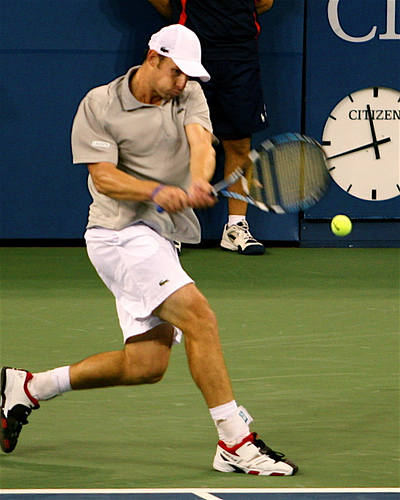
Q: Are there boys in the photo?
A: No, there are no boys.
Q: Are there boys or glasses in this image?
A: No, there are no boys or glasses.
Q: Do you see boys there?
A: No, there are no boys.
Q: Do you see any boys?
A: No, there are no boys.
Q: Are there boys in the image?
A: No, there are no boys.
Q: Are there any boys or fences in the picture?
A: No, there are no boys or fences.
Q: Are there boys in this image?
A: No, there are no boys.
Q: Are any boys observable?
A: No, there are no boys.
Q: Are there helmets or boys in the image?
A: No, there are no boys or helmets.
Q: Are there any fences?
A: No, there are no fences.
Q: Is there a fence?
A: No, there are no fences.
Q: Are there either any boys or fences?
A: No, there are no fences or boys.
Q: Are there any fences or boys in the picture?
A: No, there are no fences or boys.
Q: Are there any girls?
A: No, there are no girls.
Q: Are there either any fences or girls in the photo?
A: No, there are no girls or fences.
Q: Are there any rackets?
A: Yes, there is a racket.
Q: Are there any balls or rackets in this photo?
A: Yes, there is a racket.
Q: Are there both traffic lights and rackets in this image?
A: No, there is a racket but no traffic lights.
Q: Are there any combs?
A: No, there are no combs.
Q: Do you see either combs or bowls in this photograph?
A: No, there are no combs or bowls.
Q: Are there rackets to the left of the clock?
A: Yes, there is a racket to the left of the clock.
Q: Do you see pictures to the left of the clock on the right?
A: No, there is a racket to the left of the clock.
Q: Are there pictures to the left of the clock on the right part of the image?
A: No, there is a racket to the left of the clock.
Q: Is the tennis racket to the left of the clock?
A: Yes, the tennis racket is to the left of the clock.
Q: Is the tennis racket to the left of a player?
A: No, the tennis racket is to the left of the clock.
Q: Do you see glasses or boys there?
A: No, there are no boys or glasses.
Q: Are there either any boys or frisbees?
A: No, there are no boys or frisbees.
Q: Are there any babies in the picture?
A: No, there are no babies.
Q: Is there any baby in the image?
A: No, there are no babies.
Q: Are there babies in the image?
A: No, there are no babies.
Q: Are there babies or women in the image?
A: No, there are no babies or women.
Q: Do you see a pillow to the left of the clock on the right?
A: No, there is a man to the left of the clock.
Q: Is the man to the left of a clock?
A: Yes, the man is to the left of a clock.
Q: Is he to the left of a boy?
A: No, the man is to the left of a clock.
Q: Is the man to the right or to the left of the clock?
A: The man is to the left of the clock.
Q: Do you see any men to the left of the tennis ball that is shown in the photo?
A: Yes, there is a man to the left of the tennis ball.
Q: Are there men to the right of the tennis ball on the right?
A: No, the man is to the left of the tennis ball.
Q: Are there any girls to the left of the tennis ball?
A: No, there is a man to the left of the tennis ball.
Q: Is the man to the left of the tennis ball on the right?
A: Yes, the man is to the left of the tennis ball.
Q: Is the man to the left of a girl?
A: No, the man is to the left of the tennis ball.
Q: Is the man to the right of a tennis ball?
A: No, the man is to the left of a tennis ball.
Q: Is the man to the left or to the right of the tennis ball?
A: The man is to the left of the tennis ball.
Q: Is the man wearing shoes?
A: Yes, the man is wearing shoes.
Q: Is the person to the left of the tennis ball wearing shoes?
A: Yes, the man is wearing shoes.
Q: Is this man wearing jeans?
A: No, the man is wearing shoes.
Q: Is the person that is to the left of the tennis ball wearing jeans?
A: No, the man is wearing shoes.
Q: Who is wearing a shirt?
A: The man is wearing a shirt.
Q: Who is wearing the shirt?
A: The man is wearing a shirt.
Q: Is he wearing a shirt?
A: Yes, the man is wearing a shirt.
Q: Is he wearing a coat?
A: No, the man is wearing a shirt.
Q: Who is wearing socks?
A: The man is wearing socks.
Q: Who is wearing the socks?
A: The man is wearing socks.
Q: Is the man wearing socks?
A: Yes, the man is wearing socks.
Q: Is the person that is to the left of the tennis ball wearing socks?
A: Yes, the man is wearing socks.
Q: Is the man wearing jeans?
A: No, the man is wearing socks.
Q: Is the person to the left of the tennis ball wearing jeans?
A: No, the man is wearing socks.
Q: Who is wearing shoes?
A: The man is wearing shoes.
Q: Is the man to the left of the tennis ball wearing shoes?
A: Yes, the man is wearing shoes.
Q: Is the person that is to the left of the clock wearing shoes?
A: Yes, the man is wearing shoes.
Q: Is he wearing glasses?
A: No, the man is wearing shoes.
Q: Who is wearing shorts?
A: The man is wearing shorts.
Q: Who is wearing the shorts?
A: The man is wearing shorts.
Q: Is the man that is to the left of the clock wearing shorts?
A: Yes, the man is wearing shorts.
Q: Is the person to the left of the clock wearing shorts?
A: Yes, the man is wearing shorts.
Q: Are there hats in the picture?
A: Yes, there is a hat.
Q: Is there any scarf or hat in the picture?
A: Yes, there is a hat.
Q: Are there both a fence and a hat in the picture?
A: No, there is a hat but no fences.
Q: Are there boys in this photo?
A: No, there are no boys.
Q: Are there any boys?
A: No, there are no boys.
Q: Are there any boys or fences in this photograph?
A: No, there are no boys or fences.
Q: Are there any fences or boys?
A: No, there are no boys or fences.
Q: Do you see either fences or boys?
A: No, there are no boys or fences.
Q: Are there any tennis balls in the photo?
A: Yes, there is a tennis ball.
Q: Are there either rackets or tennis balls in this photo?
A: Yes, there is a tennis ball.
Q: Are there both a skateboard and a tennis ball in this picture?
A: No, there is a tennis ball but no skateboards.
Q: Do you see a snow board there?
A: No, there are no snowboards.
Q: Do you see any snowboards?
A: No, there are no snowboards.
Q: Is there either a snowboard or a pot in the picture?
A: No, there are no snowboards or pots.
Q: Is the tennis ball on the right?
A: Yes, the tennis ball is on the right of the image.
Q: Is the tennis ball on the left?
A: No, the tennis ball is on the right of the image.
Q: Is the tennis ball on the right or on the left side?
A: The tennis ball is on the right of the image.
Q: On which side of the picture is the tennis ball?
A: The tennis ball is on the right of the image.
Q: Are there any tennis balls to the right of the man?
A: Yes, there is a tennis ball to the right of the man.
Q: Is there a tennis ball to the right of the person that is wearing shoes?
A: Yes, there is a tennis ball to the right of the man.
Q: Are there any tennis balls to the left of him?
A: No, the tennis ball is to the right of the man.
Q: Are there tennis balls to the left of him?
A: No, the tennis ball is to the right of the man.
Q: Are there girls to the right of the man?
A: No, there is a tennis ball to the right of the man.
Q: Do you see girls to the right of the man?
A: No, there is a tennis ball to the right of the man.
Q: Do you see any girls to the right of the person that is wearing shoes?
A: No, there is a tennis ball to the right of the man.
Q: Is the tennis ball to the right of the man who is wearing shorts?
A: Yes, the tennis ball is to the right of the man.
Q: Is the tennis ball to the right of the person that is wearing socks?
A: Yes, the tennis ball is to the right of the man.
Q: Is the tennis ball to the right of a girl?
A: No, the tennis ball is to the right of the man.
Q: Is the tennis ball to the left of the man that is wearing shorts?
A: No, the tennis ball is to the right of the man.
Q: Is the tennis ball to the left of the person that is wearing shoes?
A: No, the tennis ball is to the right of the man.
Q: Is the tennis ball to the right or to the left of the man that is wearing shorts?
A: The tennis ball is to the right of the man.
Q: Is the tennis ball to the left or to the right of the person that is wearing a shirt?
A: The tennis ball is to the right of the man.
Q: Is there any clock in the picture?
A: Yes, there is a clock.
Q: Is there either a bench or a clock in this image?
A: Yes, there is a clock.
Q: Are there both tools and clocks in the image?
A: No, there is a clock but no tools.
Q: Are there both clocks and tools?
A: No, there is a clock but no tools.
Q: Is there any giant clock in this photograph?
A: Yes, there is a giant clock.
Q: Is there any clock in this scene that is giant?
A: Yes, there is a clock that is giant.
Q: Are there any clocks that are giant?
A: Yes, there is a clock that is giant.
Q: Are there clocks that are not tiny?
A: Yes, there is a giant clock.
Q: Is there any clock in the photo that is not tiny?
A: Yes, there is a giant clock.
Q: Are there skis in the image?
A: No, there are no skis.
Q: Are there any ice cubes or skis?
A: No, there are no skis or ice cubes.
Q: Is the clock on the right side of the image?
A: Yes, the clock is on the right of the image.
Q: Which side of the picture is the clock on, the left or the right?
A: The clock is on the right of the image.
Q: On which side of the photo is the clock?
A: The clock is on the right of the image.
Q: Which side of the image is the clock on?
A: The clock is on the right of the image.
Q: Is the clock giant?
A: Yes, the clock is giant.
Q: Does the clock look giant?
A: Yes, the clock is giant.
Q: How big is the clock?
A: The clock is giant.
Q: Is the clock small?
A: No, the clock is giant.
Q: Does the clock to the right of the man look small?
A: No, the clock is giant.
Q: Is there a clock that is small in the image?
A: No, there is a clock but it is giant.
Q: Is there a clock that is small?
A: No, there is a clock but it is giant.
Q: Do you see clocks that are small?
A: No, there is a clock but it is giant.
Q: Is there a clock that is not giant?
A: No, there is a clock but it is giant.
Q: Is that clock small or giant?
A: The clock is giant.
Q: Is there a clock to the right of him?
A: Yes, there is a clock to the right of the man.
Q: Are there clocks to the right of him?
A: Yes, there is a clock to the right of the man.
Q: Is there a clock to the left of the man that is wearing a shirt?
A: No, the clock is to the right of the man.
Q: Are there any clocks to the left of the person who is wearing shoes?
A: No, the clock is to the right of the man.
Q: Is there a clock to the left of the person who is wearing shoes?
A: No, the clock is to the right of the man.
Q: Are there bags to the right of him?
A: No, there is a clock to the right of the man.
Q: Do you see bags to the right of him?
A: No, there is a clock to the right of the man.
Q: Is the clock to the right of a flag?
A: No, the clock is to the right of the man.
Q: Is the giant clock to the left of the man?
A: No, the clock is to the right of the man.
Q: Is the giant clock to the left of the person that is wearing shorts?
A: No, the clock is to the right of the man.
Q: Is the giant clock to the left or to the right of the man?
A: The clock is to the right of the man.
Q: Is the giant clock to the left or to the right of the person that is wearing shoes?
A: The clock is to the right of the man.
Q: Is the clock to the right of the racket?
A: Yes, the clock is to the right of the racket.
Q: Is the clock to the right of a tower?
A: No, the clock is to the right of the racket.